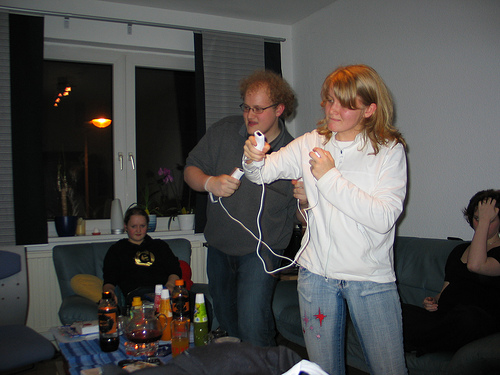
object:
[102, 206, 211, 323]
woman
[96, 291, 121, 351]
bottle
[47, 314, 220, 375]
table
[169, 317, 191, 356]
glass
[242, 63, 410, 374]
person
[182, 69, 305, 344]
man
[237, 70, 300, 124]
hair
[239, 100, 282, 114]
glasses.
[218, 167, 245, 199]
wii controller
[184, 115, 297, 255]
shirt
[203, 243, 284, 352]
jeans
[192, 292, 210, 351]
drinks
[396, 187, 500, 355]
girl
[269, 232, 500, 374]
sofa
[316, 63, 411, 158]
hair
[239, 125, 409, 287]
jacket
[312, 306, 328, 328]
red star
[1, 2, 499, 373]
party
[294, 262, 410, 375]
jeans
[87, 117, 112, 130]
light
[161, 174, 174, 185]
flowers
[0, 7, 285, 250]
window